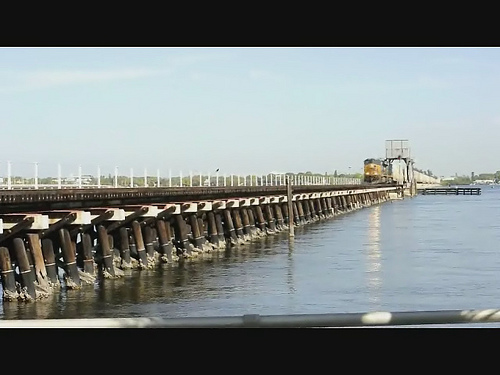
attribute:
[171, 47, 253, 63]
cloud — white 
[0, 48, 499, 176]
sky — blue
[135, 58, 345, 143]
sky —  blue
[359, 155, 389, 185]
train engine — yellow train 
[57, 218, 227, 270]
pylons — wooden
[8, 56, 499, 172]
sky — blue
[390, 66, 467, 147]
cloud — white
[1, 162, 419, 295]
bridge — wooden train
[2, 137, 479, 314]
bridge — rail 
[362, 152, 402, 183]
train — black, yellow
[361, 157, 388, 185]
train — yellow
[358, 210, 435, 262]
water — dark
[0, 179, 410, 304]
bridge — brown wooden 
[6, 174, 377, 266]
rail bridge — rail 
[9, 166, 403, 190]
white fence —  white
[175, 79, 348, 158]
clouds — white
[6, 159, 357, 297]
pier — long wooden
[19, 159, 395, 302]
bridge — wooden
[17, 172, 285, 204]
tracks —  train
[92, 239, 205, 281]
support — wooden 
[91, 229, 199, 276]
support — wooden